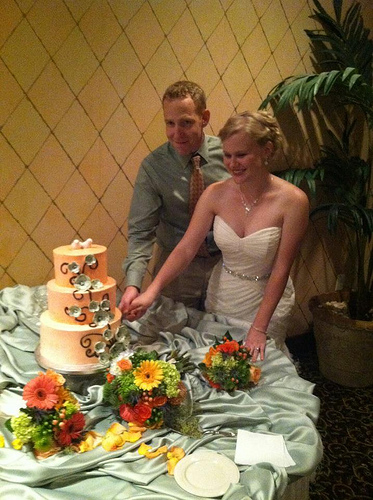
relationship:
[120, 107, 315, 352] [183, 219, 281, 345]
woman in dress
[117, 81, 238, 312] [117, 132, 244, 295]
man wearing shirt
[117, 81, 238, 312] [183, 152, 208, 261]
man wearing tie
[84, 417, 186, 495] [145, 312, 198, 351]
petals on table cloth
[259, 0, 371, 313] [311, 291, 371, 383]
plant in brown pot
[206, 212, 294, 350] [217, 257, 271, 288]
dress with belt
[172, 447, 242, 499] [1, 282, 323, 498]
white plate on table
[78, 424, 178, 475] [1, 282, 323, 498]
rose petals on table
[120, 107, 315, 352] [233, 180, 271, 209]
woman wearing necklace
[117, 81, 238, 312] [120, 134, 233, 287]
man wearing shirt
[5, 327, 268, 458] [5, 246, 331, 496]
bouquets on table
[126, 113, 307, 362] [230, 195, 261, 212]
bride wearing necklace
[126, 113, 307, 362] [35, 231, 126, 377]
bride cutting cake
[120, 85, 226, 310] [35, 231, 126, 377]
groom cutting cake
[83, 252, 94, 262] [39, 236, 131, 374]
flower on cake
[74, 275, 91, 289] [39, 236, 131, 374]
flower on cake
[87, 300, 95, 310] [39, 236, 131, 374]
flower on cake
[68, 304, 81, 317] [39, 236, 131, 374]
flower on cake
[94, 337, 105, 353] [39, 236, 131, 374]
flower on cake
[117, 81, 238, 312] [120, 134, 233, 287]
man wears shirt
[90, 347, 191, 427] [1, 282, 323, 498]
flowers on table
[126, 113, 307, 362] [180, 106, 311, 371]
bride wearing dress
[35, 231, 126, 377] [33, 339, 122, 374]
cake on plate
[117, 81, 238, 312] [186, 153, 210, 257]
man wearing tie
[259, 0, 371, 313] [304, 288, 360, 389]
plant in pot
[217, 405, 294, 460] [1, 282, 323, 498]
napkin on table